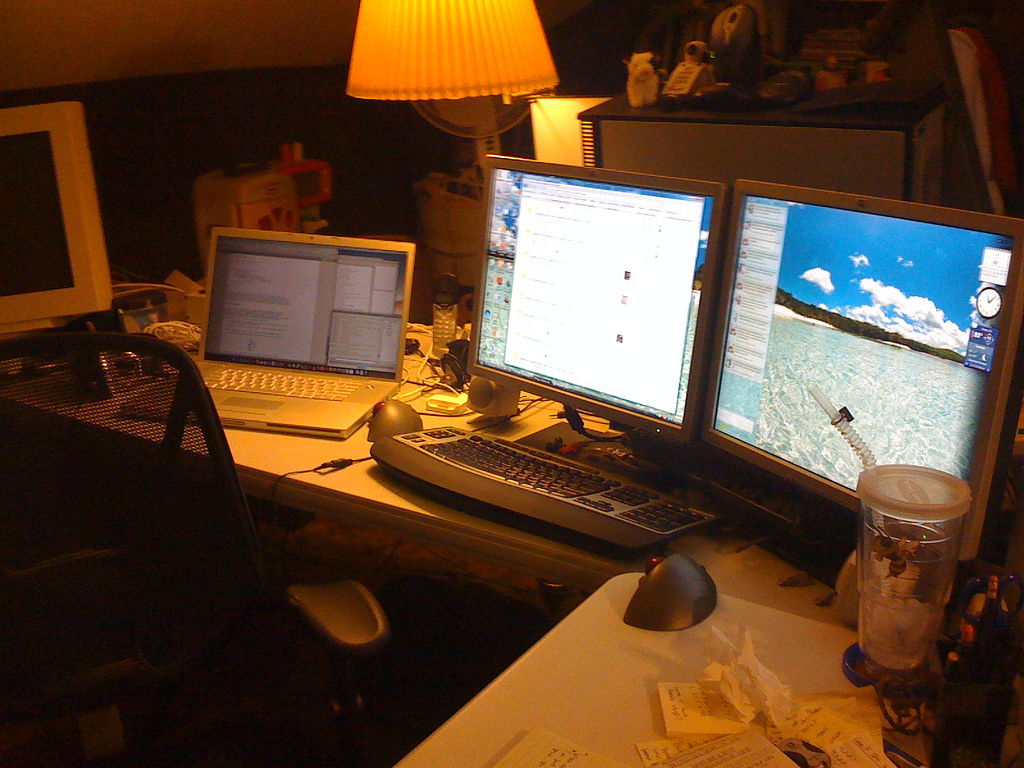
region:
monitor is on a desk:
[477, 150, 725, 442]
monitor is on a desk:
[703, 173, 1018, 563]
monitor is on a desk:
[1, 110, 110, 333]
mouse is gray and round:
[630, 556, 722, 636]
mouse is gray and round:
[368, 398, 419, 441]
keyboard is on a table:
[376, 425, 719, 563]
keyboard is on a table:
[130, 363, 400, 431]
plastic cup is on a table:
[857, 464, 966, 683]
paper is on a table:
[654, 662, 756, 729]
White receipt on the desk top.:
[645, 632, 867, 746]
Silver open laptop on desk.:
[139, 222, 425, 451]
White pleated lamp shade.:
[343, 0, 552, 95]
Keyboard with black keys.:
[373, 417, 713, 553]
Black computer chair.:
[11, 338, 354, 728]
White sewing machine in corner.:
[192, 133, 338, 258]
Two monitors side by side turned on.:
[458, 146, 1013, 579]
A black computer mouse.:
[616, 555, 724, 631]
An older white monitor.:
[5, 90, 103, 331]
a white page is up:
[431, 125, 692, 427]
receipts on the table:
[624, 612, 859, 761]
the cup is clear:
[782, 361, 959, 698]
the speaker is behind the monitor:
[450, 343, 537, 423]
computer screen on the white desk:
[2, 125, 69, 302]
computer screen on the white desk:
[209, 236, 394, 376]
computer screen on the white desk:
[469, 168, 711, 429]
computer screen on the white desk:
[712, 193, 1006, 513]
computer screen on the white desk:
[197, 230, 407, 380]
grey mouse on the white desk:
[623, 557, 716, 644]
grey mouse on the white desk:
[356, 391, 430, 450]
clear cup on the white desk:
[845, 465, 983, 685]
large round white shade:
[340, 3, 565, 103]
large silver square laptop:
[113, 217, 423, 445]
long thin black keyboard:
[372, 419, 734, 566]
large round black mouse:
[622, 551, 722, 628]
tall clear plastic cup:
[849, 463, 980, 678]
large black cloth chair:
[0, 331, 396, 765]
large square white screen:
[1, 94, 109, 339]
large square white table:
[393, 567, 1023, 765]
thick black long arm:
[280, 568, 394, 655]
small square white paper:
[652, 678, 761, 743]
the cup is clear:
[849, 461, 971, 668]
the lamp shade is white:
[343, 0, 558, 99]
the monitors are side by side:
[471, 154, 1022, 560]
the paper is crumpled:
[700, 613, 800, 730]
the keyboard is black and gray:
[365, 420, 713, 556]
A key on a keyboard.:
[530, 462, 551, 482]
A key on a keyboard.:
[457, 438, 473, 449]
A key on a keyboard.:
[474, 450, 485, 464]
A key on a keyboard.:
[498, 453, 517, 467]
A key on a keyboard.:
[654, 507, 670, 520]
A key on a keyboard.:
[622, 488, 633, 499]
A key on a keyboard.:
[256, 371, 272, 378]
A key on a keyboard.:
[287, 377, 307, 391]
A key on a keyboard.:
[223, 380, 234, 390]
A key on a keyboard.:
[458, 452, 471, 460]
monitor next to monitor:
[712, 175, 1020, 562]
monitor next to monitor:
[472, 146, 725, 453]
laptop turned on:
[124, 222, 413, 437]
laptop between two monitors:
[106, 213, 416, 441]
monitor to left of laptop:
[1, 98, 125, 343]